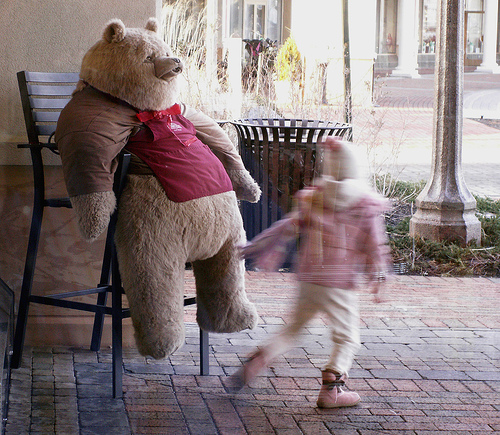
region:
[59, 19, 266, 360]
big brown teddy bear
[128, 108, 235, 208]
wine apron of big teddy bear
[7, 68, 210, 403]
black chair where teddy bear is seated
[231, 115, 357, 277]
black metal garbage can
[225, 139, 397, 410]
little blurred blonde girl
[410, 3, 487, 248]
black lamppost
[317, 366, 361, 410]
black and pink right boot of little girl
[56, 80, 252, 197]
brown t-shirt of teddy bear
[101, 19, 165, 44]
two small furry ears of teddy bear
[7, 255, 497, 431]
brick road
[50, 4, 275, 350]
teddy bear sitting in chair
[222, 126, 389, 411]
girl running by teddy bear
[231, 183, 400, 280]
pink coat of girl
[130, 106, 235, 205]
red apron on teddy bear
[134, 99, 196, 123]
red bowtie on teddy bear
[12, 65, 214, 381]
chair bear is sitting in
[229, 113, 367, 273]
trash can next to teddy bear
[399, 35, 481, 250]
gray lamp post beside trash can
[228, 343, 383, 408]
pink boots of little girl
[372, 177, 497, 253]
grass surrounding lamp post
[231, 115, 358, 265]
Big black trash garbage receptacle.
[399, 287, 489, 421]
Multi colored brick patio.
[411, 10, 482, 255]
Concrete base of a street light pole.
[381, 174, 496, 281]
Weeds growing on the side of the streets.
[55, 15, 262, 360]
Big bear sitting on a black chair.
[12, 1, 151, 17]
Beige colored painted wall.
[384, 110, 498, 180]
Shadows on the side of the sidewalk.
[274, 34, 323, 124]
Tree with foilage growing on side of street.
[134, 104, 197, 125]
Red and white bow tie on top of red apron.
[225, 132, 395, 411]
Little girl wearing pink jacket and white pants.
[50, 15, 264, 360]
A giant brown bear with red apron on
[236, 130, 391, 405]
A small girl with pink coat on.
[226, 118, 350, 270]
A large metal framed waste basket.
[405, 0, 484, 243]
A tall concrete pole to the front right of a girl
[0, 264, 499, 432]
A brick walkway under the girl and bear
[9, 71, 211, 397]
Tall metal chair with a bear on it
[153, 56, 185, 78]
Snout and mouth of a big bear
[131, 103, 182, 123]
Red bowtie on a bear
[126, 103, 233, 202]
Red apron on a huge brown bear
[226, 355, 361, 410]
Pink boots with brown bows on boots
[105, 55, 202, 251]
huge teddy bear is tan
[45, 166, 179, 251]
teddy bear is sitting in a chair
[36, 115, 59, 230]
chair is black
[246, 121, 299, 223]
trash can is next to the pole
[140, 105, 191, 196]
teddy bear has a red apron on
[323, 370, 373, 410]
girl has pink boots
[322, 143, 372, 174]
girl is wearing a pink hat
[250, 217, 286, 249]
girl is wearing a scarf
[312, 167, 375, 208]
girl has a hood on her jacket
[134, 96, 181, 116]
teddy bear has bow tie